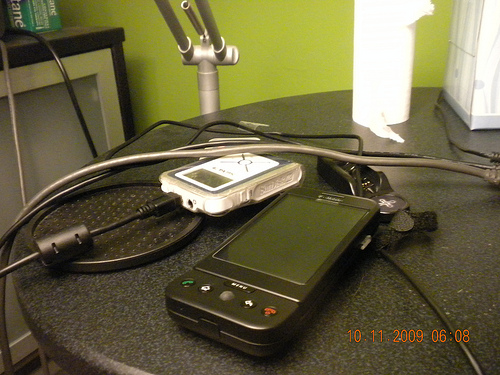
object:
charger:
[33, 182, 198, 272]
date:
[345, 328, 471, 344]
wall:
[54, 0, 450, 139]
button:
[198, 283, 214, 294]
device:
[158, 145, 303, 208]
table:
[11, 87, 500, 373]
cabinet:
[7, 24, 122, 369]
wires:
[436, 102, 491, 161]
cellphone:
[166, 187, 380, 357]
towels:
[348, 0, 432, 144]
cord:
[3, 192, 181, 273]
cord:
[10, 140, 487, 224]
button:
[261, 303, 278, 316]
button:
[180, 277, 196, 287]